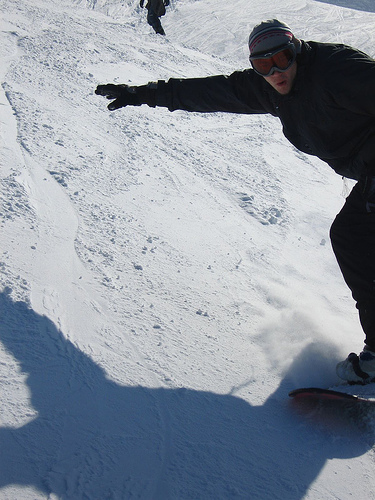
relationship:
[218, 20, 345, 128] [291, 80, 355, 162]
man wearing jacket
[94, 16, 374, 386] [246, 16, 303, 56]
man wearing hat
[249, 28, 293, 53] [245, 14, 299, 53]
stripe on hat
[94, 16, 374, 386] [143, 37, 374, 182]
man wearing jacket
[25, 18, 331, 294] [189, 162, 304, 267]
ground covered in snow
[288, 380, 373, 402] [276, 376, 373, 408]
snowboard with rim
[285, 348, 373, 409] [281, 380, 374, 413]
snow on top of snowboard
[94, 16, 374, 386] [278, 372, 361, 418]
man on snowboard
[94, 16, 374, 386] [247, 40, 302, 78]
man wearing goggles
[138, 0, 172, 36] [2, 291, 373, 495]
man has shadow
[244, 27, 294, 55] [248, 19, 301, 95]
beanie on head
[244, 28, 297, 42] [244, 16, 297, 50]
stripe in hat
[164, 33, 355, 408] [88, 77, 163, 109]
man wearing glove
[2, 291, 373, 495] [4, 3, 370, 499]
shadow on snow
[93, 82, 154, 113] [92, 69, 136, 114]
glove covered hand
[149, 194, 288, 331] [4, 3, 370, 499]
tracks on snow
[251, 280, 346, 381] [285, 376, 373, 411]
snow flying around snowboarder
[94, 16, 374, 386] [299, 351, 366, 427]
man on snowboard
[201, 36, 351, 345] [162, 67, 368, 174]
man wearing jacket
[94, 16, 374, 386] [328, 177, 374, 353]
man wearing pants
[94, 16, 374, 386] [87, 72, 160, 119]
man wearing glove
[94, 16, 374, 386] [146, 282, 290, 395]
man in snow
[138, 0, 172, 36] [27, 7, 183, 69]
man in background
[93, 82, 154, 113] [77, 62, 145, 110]
glove on hand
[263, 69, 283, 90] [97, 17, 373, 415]
nose of a man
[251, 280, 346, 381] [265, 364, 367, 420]
snow thrown in air from snowboard